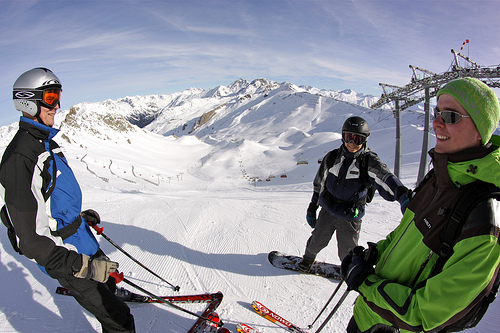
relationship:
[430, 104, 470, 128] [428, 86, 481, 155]
glasses on face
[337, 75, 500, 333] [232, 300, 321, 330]
adult on skiis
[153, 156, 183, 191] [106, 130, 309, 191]
snow on hill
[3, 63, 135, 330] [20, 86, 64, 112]
man wearing goggles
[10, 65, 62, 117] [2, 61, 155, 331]
helmet on man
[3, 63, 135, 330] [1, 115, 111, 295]
man wearing jacket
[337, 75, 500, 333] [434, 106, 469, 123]
adult wearing glasses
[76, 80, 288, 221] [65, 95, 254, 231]
mountain with snow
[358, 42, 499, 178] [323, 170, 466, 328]
adult in suit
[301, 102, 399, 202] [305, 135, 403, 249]
adult in suit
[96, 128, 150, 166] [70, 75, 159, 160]
snow on mountain side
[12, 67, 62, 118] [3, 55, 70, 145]
helmet on head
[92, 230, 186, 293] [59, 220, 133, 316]
ski pole in hand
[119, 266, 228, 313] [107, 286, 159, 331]
skis on feet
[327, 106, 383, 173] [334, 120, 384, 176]
helmet on head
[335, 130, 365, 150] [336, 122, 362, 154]
ski goggles on face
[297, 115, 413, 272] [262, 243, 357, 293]
adult on snowboard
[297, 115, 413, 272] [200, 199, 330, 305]
adult on mountain top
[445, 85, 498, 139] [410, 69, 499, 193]
hat on man's head